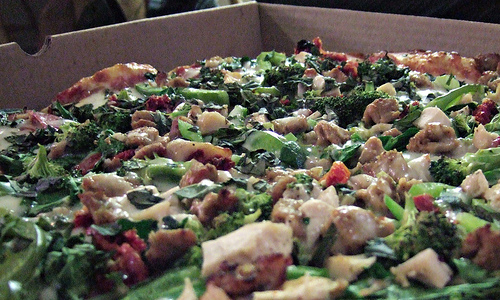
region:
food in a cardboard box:
[1, 5, 496, 299]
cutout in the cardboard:
[16, 35, 56, 58]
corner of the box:
[254, 0, 279, 57]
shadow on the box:
[259, 8, 294, 49]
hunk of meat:
[189, 224, 306, 293]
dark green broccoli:
[57, 113, 109, 160]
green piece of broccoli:
[380, 200, 465, 265]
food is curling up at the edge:
[41, 56, 166, 94]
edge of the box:
[263, 0, 498, 32]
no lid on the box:
[0, 0, 499, 298]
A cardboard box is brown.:
[2, 2, 499, 109]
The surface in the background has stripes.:
[0, 0, 498, 48]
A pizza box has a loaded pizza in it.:
[0, 0, 496, 295]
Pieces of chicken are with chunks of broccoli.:
[180, 120, 431, 280]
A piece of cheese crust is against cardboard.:
[50, 57, 167, 102]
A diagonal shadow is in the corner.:
[236, 4, 293, 55]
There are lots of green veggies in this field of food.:
[0, 40, 499, 299]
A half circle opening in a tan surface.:
[14, 33, 53, 56]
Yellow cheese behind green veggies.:
[309, 37, 484, 87]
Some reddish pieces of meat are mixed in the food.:
[0, 37, 499, 297]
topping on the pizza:
[125, 204, 187, 256]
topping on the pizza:
[336, 229, 396, 275]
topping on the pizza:
[360, 150, 424, 203]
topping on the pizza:
[268, 143, 298, 186]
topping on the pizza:
[368, 103, 433, 159]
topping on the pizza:
[198, 174, 265, 216]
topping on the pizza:
[346, 130, 399, 168]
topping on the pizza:
[76, 185, 153, 245]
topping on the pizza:
[229, 108, 284, 140]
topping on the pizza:
[91, 153, 152, 204]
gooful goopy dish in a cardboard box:
[3, 0, 498, 296]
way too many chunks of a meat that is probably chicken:
[181, 107, 491, 297]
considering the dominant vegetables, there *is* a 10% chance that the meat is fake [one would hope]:
[56, 69, 453, 298]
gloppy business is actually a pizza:
[0, 26, 499, 298]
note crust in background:
[34, 21, 496, 110]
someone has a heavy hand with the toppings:
[0, 46, 499, 298]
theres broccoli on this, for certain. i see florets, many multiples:
[10, 52, 477, 264]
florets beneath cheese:
[265, 53, 445, 140]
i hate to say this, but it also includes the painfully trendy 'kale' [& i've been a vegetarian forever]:
[85, 46, 429, 155]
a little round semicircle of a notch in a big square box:
[12, 25, 62, 65]